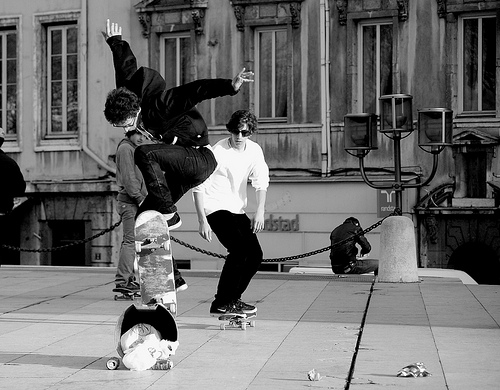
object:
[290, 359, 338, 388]
trash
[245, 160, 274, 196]
sleeves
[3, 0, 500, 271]
building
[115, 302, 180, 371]
trash can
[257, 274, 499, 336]
ground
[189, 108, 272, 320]
boy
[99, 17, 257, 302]
boy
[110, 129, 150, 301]
boy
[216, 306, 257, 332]
skateboard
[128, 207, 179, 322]
skateboard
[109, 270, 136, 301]
skateboard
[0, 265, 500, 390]
sidewalk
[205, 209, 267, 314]
pants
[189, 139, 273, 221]
shirt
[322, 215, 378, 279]
man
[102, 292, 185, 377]
garbage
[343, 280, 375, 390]
crack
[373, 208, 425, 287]
concrete structure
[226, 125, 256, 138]
sunglasses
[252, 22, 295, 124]
window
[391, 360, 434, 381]
garbage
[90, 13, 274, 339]
teen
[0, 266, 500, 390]
ground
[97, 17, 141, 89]
arm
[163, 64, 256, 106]
arm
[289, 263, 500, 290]
ledge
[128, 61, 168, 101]
hoodie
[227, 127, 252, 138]
glasses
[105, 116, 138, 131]
glasses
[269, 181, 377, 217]
wall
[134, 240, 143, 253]
wheels